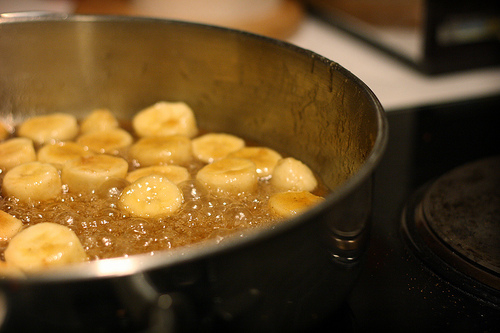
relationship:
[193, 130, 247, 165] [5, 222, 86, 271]
slice of banana slice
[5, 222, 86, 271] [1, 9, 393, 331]
banana slice in pan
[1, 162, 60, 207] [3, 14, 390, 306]
slice in pan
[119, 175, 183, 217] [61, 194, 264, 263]
banana slice in oil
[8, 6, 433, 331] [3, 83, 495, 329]
pan on stove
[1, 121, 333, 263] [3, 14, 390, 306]
liquid in pan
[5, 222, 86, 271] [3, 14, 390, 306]
banana slice in pan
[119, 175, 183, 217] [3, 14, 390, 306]
banana slice in pan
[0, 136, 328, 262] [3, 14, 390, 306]
liquid in pan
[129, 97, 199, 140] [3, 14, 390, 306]
banana cooking in pan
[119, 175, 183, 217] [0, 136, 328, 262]
banana slice sauteed in liquid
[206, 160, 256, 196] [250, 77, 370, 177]
banana slice in pan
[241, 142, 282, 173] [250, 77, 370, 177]
banana slice in pan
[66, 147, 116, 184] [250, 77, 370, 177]
banana slice in pan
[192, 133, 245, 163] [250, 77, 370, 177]
slice in pan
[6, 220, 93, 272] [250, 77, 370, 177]
banana slice in pan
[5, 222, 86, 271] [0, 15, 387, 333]
banana slice in pan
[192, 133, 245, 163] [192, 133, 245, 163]
slice of slice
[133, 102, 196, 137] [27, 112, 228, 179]
banana of banana